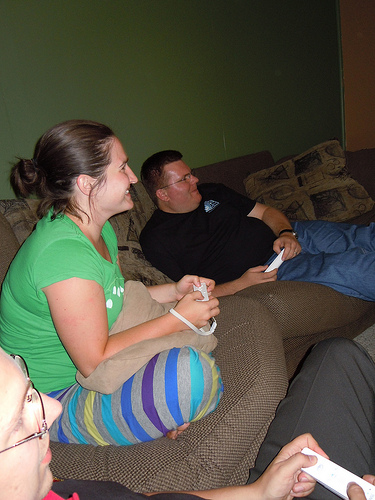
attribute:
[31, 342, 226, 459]
pants — grey, striped, warm up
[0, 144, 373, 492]
brown sofa — cloth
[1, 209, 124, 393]
t-shirt — green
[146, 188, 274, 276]
shirt — black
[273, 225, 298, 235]
watch — black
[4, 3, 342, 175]
wall — green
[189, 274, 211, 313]
controller — wii hand game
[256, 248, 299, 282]
controller — wii hand game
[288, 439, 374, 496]
controller — wii hand game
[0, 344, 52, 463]
glasses — wire rim , eye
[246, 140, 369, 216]
sofa — beige and brown, pillow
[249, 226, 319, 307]
controller — game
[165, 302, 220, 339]
controller strap — wii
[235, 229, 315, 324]
controller — wii game, wrist strap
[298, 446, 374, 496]
controller — wii, game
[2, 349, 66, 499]
face — man's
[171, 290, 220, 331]
hand — woman's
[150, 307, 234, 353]
strap — white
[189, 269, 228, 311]
controller — video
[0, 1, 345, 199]
wall — green, in the background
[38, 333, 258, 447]
pants — striped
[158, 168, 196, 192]
glasses — wire rim eye 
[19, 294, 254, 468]
pajama — striped, pants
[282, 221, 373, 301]
jeans — blue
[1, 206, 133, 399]
shirt — green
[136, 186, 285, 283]
shirt — black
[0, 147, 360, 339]
couch — patterened